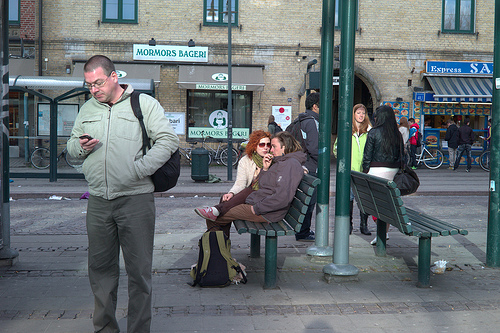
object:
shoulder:
[365, 124, 402, 140]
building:
[0, 0, 500, 159]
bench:
[348, 169, 470, 289]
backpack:
[393, 153, 420, 197]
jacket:
[362, 123, 409, 174]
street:
[3, 189, 499, 234]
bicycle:
[29, 138, 86, 170]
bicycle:
[179, 129, 241, 167]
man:
[408, 117, 423, 170]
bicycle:
[402, 137, 446, 170]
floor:
[0, 161, 500, 333]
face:
[256, 137, 273, 157]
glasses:
[257, 142, 271, 148]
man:
[205, 131, 310, 237]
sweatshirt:
[244, 150, 308, 225]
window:
[182, 86, 255, 149]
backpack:
[187, 227, 248, 289]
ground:
[0, 157, 500, 333]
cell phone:
[79, 135, 93, 141]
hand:
[79, 134, 100, 152]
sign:
[132, 43, 208, 63]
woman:
[362, 104, 421, 244]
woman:
[332, 103, 376, 236]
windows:
[95, 0, 243, 28]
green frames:
[435, 0, 478, 36]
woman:
[193, 129, 273, 225]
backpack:
[131, 89, 183, 193]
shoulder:
[129, 93, 159, 116]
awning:
[426, 76, 492, 97]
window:
[438, 0, 477, 35]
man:
[64, 54, 181, 333]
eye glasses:
[82, 69, 115, 90]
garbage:
[48, 193, 72, 201]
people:
[193, 125, 308, 238]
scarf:
[249, 151, 273, 190]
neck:
[255, 155, 264, 161]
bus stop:
[0, 0, 500, 332]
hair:
[245, 130, 272, 160]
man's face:
[83, 68, 115, 104]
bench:
[231, 172, 322, 291]